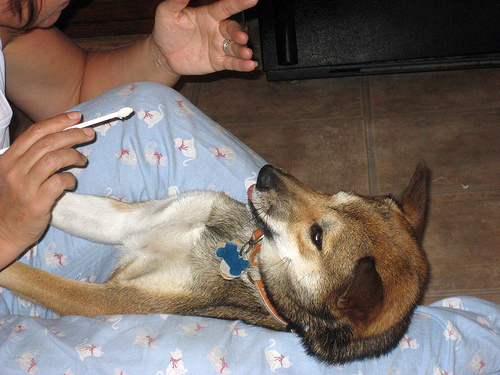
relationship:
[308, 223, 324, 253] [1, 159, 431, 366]
eye on dog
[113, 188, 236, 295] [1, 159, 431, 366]
chest on dog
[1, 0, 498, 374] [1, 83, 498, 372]
person wears pants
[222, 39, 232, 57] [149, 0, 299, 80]
ring in hand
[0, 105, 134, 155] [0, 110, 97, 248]
swab on right hand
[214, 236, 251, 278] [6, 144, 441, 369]
tags on dog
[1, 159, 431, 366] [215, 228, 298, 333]
dog wears collar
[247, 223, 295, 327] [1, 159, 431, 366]
collar on dog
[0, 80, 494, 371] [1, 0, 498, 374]
pajamas on person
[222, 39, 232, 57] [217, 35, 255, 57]
ring on finger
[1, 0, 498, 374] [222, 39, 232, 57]
person wears ring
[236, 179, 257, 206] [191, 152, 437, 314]
tip on dog's tongue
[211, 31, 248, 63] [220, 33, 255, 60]
ring on finger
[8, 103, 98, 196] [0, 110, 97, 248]
fingers on right hand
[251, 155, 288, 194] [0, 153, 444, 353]
nose on dog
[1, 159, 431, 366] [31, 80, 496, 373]
dog laying on lap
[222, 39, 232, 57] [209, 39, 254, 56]
ring on finger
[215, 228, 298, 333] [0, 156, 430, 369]
collar on dog